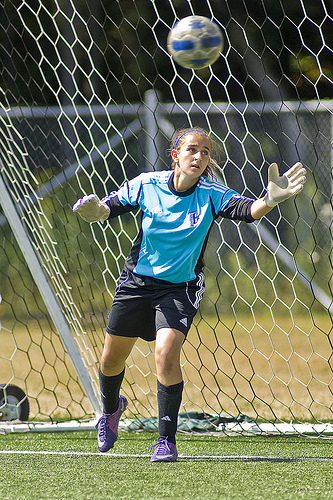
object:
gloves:
[262, 162, 307, 203]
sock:
[155, 379, 183, 441]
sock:
[97, 367, 124, 410]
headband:
[173, 123, 209, 146]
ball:
[167, 15, 223, 70]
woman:
[71, 125, 306, 460]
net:
[11, 11, 330, 421]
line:
[17, 442, 323, 465]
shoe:
[150, 436, 176, 462]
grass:
[30, 437, 300, 499]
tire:
[1, 382, 30, 422]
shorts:
[107, 271, 204, 339]